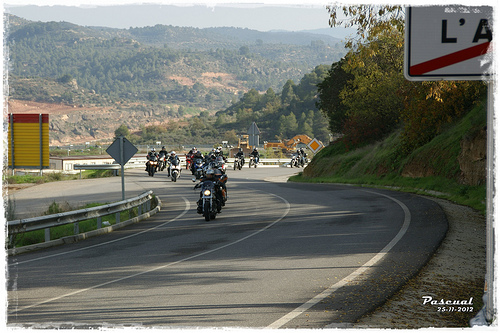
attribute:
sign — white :
[401, 6, 491, 82]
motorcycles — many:
[132, 113, 282, 258]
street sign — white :
[401, 0, 493, 81]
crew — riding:
[121, 136, 308, 218]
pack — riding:
[108, 139, 314, 223]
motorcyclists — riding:
[143, 131, 319, 231]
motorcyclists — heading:
[128, 140, 318, 238]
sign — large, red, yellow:
[10, 110, 71, 186]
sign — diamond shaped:
[95, 131, 155, 163]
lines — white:
[78, 190, 407, 320]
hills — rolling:
[53, 9, 290, 85]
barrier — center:
[29, 188, 165, 268]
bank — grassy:
[318, 82, 475, 207]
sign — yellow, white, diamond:
[295, 133, 320, 158]